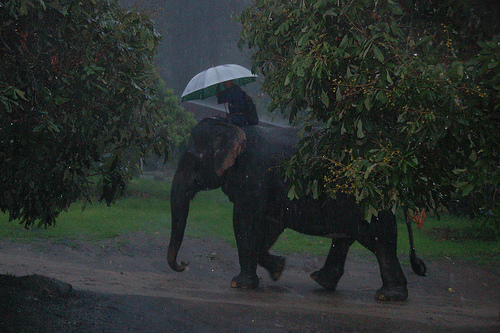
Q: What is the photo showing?
A: It is showing a path.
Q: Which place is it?
A: It is a path.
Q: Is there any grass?
A: Yes, there is grass.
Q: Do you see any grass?
A: Yes, there is grass.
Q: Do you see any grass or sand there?
A: Yes, there is grass.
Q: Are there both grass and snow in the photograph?
A: No, there is grass but no snow.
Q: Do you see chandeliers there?
A: No, there are no chandeliers.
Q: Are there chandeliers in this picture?
A: No, there are no chandeliers.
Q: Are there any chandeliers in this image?
A: No, there are no chandeliers.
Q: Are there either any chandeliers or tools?
A: No, there are no chandeliers or tools.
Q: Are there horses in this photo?
A: No, there are no horses.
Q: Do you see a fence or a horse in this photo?
A: No, there are no horses or fences.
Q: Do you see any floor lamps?
A: No, there are no floor lamps.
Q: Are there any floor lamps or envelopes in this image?
A: No, there are no floor lamps or envelopes.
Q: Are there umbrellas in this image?
A: Yes, there is an umbrella.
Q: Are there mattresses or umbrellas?
A: Yes, there is an umbrella.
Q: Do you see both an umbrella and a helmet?
A: No, there is an umbrella but no helmets.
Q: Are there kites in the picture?
A: No, there are no kites.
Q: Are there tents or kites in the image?
A: No, there are no kites or tents.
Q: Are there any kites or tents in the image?
A: No, there are no kites or tents.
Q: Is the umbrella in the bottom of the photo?
A: No, the umbrella is in the top of the image.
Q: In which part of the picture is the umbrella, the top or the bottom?
A: The umbrella is in the top of the image.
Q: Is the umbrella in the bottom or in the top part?
A: The umbrella is in the top of the image.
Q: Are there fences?
A: No, there are no fences.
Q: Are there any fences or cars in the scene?
A: No, there are no fences or cars.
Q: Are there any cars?
A: No, there are no cars.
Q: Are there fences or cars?
A: No, there are no cars or fences.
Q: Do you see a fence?
A: No, there are no fences.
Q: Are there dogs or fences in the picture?
A: No, there are no fences or dogs.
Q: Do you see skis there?
A: No, there are no skis.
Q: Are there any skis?
A: No, there are no skis.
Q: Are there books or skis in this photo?
A: No, there are no skis or books.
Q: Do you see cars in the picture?
A: No, there are no cars.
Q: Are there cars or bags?
A: No, there are no cars or bags.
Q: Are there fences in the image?
A: No, there are no fences.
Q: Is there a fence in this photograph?
A: No, there are no fences.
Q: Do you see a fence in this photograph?
A: No, there are no fences.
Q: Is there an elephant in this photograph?
A: Yes, there is an elephant.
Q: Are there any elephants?
A: Yes, there is an elephant.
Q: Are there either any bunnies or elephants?
A: Yes, there is an elephant.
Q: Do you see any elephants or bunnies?
A: Yes, there is an elephant.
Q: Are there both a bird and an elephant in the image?
A: No, there is an elephant but no birds.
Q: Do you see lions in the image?
A: No, there are no lions.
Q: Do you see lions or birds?
A: No, there are no lions or birds.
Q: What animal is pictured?
A: The animal is an elephant.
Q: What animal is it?
A: The animal is an elephant.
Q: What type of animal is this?
A: This is an elephant.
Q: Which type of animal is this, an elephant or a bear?
A: This is an elephant.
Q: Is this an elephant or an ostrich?
A: This is an elephant.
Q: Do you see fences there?
A: No, there are no fences.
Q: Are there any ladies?
A: No, there are no ladies.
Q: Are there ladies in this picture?
A: No, there are no ladies.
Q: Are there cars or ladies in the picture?
A: No, there are no ladies or cars.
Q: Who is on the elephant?
A: The driver is on the elephant.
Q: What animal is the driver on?
A: The driver is on the elephant.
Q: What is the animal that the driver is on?
A: The animal is an elephant.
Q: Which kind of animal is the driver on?
A: The driver is on the elephant.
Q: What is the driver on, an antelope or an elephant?
A: The driver is on an elephant.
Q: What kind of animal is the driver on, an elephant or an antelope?
A: The driver is on an elephant.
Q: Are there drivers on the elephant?
A: Yes, there is a driver on the elephant.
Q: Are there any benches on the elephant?
A: No, there is a driver on the elephant.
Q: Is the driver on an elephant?
A: Yes, the driver is on an elephant.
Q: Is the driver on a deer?
A: No, the driver is on an elephant.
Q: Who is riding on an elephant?
A: The driver is riding on an elephant.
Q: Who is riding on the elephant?
A: The driver is riding on an elephant.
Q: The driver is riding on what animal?
A: The driver is riding on an elephant.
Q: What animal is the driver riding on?
A: The driver is riding on an elephant.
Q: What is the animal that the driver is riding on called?
A: The animal is an elephant.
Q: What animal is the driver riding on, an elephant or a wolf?
A: The driver is riding on an elephant.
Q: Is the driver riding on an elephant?
A: Yes, the driver is riding on an elephant.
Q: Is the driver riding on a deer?
A: No, the driver is riding on an elephant.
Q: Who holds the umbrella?
A: The driver holds the umbrella.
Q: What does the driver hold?
A: The driver holds the umbrella.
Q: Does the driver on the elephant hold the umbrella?
A: Yes, the driver holds the umbrella.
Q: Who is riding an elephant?
A: The driver is riding an elephant.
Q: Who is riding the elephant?
A: The driver is riding an elephant.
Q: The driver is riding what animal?
A: The driver is riding an elephant.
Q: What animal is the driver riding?
A: The driver is riding an elephant.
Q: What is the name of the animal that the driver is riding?
A: The animal is an elephant.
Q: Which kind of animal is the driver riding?
A: The driver is riding an elephant.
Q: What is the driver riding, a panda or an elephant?
A: The driver is riding an elephant.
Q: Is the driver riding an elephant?
A: Yes, the driver is riding an elephant.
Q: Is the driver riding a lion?
A: No, the driver is riding an elephant.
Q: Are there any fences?
A: No, there are no fences.